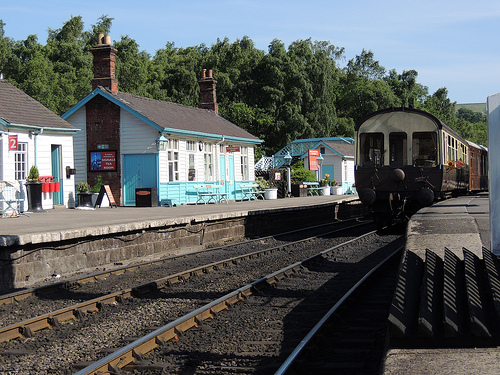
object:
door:
[51, 146, 62, 207]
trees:
[0, 12, 490, 166]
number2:
[10, 139, 17, 149]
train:
[353, 108, 488, 228]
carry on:
[353, 104, 479, 234]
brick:
[102, 113, 113, 118]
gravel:
[184, 320, 263, 373]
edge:
[161, 126, 265, 145]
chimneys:
[197, 69, 218, 115]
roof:
[60, 84, 266, 146]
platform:
[0, 193, 365, 297]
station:
[0, 91, 497, 375]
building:
[0, 68, 82, 213]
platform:
[388, 185, 500, 375]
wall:
[0, 250, 146, 284]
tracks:
[0, 214, 407, 375]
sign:
[87, 149, 119, 173]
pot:
[24, 182, 50, 214]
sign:
[94, 184, 118, 209]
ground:
[66, 201, 129, 223]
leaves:
[250, 55, 338, 106]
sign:
[8, 134, 18, 151]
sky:
[0, 0, 499, 105]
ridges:
[382, 245, 498, 350]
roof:
[0, 78, 82, 130]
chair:
[193, 184, 230, 205]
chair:
[240, 183, 267, 202]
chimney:
[88, 31, 119, 94]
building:
[61, 32, 266, 209]